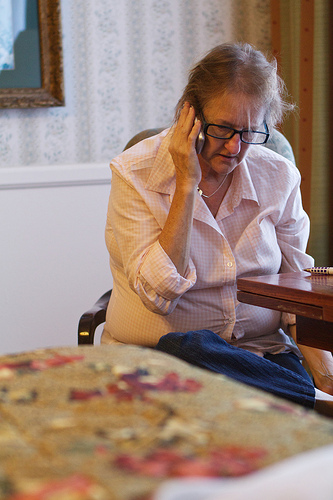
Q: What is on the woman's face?
A: Glasses.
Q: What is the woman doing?
A: Talking on phone.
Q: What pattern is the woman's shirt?
A: Checked.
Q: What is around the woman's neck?
A: Necklace.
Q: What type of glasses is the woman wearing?
A: Black.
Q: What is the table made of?
A: Wood.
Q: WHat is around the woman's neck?
A: A necklace.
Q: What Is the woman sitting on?
A: A chair.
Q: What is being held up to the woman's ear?
A: A cell phone.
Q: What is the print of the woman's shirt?
A: Pink and white checked.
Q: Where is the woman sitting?
A: At the table.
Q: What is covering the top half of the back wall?
A: Wallpaper.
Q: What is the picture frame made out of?
A: Wood.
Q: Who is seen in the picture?
A: Old lady.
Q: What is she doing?
A: Talking in phone.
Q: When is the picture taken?
A: Daytime.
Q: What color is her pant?
A: Blue.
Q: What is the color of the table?
A: Brown.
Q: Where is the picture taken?
A: In a house.